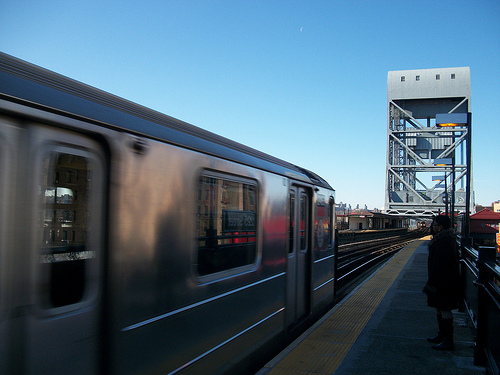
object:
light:
[435, 112, 469, 128]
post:
[465, 112, 472, 248]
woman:
[422, 215, 463, 350]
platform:
[250, 234, 499, 374]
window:
[197, 171, 257, 284]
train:
[1, 52, 341, 375]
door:
[0, 107, 118, 375]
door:
[283, 184, 314, 328]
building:
[195, 177, 257, 243]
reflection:
[266, 217, 295, 265]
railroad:
[334, 228, 429, 302]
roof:
[468, 208, 500, 220]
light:
[434, 158, 454, 166]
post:
[452, 132, 455, 228]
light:
[430, 175, 444, 182]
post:
[444, 169, 448, 216]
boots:
[431, 317, 455, 351]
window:
[35, 143, 107, 308]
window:
[289, 192, 294, 256]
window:
[300, 195, 307, 251]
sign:
[223, 211, 257, 232]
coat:
[421, 228, 468, 309]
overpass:
[384, 209, 463, 217]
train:
[419, 220, 428, 229]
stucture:
[384, 65, 472, 219]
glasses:
[432, 223, 443, 227]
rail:
[455, 237, 499, 374]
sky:
[1, 1, 500, 210]